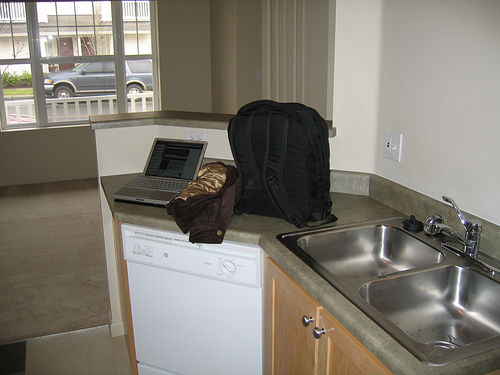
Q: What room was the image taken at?
A: It was taken at the kitchen.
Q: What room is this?
A: It is a kitchen.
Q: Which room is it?
A: It is a kitchen.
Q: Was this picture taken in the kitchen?
A: Yes, it was taken in the kitchen.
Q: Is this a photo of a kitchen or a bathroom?
A: It is showing a kitchen.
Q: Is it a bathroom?
A: No, it is a kitchen.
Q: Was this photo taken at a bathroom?
A: No, the picture was taken in a kitchen.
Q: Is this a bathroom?
A: No, it is a kitchen.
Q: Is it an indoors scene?
A: Yes, it is indoors.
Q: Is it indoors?
A: Yes, it is indoors.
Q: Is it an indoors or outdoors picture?
A: It is indoors.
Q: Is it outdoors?
A: No, it is indoors.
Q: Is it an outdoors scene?
A: No, it is indoors.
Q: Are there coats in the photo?
A: Yes, there is a coat.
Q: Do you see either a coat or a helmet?
A: Yes, there is a coat.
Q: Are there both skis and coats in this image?
A: No, there is a coat but no skis.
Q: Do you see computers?
A: Yes, there is a computer.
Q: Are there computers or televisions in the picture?
A: Yes, there is a computer.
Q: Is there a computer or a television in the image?
A: Yes, there is a computer.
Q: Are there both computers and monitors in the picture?
A: No, there is a computer but no monitors.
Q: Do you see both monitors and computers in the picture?
A: No, there is a computer but no monitors.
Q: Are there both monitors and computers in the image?
A: No, there is a computer but no monitors.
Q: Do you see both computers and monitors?
A: No, there is a computer but no monitors.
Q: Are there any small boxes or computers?
A: Yes, there is a small computer.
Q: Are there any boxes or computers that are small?
A: Yes, the computer is small.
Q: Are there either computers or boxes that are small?
A: Yes, the computer is small.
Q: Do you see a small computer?
A: Yes, there is a small computer.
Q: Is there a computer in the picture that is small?
A: Yes, there is a computer that is small.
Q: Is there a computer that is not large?
A: Yes, there is a small computer.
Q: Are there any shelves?
A: No, there are no shelves.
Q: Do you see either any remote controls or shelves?
A: No, there are no shelves or remote controls.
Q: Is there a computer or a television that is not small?
A: No, there is a computer but it is small.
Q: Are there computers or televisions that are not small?
A: No, there is a computer but it is small.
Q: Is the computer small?
A: Yes, the computer is small.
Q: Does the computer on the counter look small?
A: Yes, the computer is small.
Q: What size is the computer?
A: The computer is small.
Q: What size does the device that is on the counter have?
A: The computer has small size.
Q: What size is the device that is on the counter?
A: The computer is small.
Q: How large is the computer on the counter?
A: The computer is small.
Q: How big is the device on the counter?
A: The computer is small.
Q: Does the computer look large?
A: No, the computer is small.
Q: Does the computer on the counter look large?
A: No, the computer is small.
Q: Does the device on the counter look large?
A: No, the computer is small.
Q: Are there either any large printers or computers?
A: No, there is a computer but it is small.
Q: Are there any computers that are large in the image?
A: No, there is a computer but it is small.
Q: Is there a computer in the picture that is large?
A: No, there is a computer but it is small.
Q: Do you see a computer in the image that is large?
A: No, there is a computer but it is small.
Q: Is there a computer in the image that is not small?
A: No, there is a computer but it is small.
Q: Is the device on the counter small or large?
A: The computer is small.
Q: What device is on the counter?
A: The device is a computer.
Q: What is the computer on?
A: The computer is on the counter.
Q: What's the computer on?
A: The computer is on the counter.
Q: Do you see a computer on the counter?
A: Yes, there is a computer on the counter.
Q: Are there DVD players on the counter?
A: No, there is a computer on the counter.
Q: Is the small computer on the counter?
A: Yes, the computer is on the counter.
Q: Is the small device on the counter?
A: Yes, the computer is on the counter.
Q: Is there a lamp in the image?
A: No, there are no lamps.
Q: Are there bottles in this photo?
A: No, there are no bottles.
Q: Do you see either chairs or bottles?
A: No, there are no bottles or chairs.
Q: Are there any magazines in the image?
A: No, there are no magazines.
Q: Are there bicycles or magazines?
A: No, there are no magazines or bicycles.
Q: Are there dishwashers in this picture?
A: Yes, there is a dishwasher.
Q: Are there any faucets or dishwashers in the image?
A: Yes, there is a dishwasher.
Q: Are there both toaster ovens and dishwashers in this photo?
A: No, there is a dishwasher but no toaster ovens.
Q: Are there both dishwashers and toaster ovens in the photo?
A: No, there is a dishwasher but no toaster ovens.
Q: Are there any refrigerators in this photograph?
A: No, there are no refrigerators.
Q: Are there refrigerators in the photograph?
A: No, there are no refrigerators.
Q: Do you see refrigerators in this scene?
A: No, there are no refrigerators.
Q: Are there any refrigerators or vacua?
A: No, there are no refrigerators or vacua.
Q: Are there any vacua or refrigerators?
A: No, there are no refrigerators or vacua.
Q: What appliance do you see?
A: The appliance is a dishwasher.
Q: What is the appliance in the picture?
A: The appliance is a dishwasher.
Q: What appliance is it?
A: The appliance is a dishwasher.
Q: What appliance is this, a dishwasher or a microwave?
A: This is a dishwasher.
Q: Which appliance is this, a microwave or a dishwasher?
A: This is a dishwasher.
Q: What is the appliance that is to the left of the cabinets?
A: The appliance is a dishwasher.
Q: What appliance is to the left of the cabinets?
A: The appliance is a dishwasher.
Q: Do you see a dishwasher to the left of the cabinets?
A: Yes, there is a dishwasher to the left of the cabinets.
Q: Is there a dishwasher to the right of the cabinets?
A: No, the dishwasher is to the left of the cabinets.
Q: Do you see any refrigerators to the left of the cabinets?
A: No, there is a dishwasher to the left of the cabinets.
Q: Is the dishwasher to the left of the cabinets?
A: Yes, the dishwasher is to the left of the cabinets.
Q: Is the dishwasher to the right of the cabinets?
A: No, the dishwasher is to the left of the cabinets.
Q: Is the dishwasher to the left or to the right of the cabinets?
A: The dishwasher is to the left of the cabinets.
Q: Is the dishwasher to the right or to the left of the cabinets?
A: The dishwasher is to the left of the cabinets.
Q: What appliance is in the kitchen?
A: The appliance is a dishwasher.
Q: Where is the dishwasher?
A: The dishwasher is in the kitchen.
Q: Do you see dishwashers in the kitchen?
A: Yes, there is a dishwasher in the kitchen.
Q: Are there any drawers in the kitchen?
A: No, there is a dishwasher in the kitchen.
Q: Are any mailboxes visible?
A: No, there are no mailboxes.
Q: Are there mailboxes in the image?
A: No, there are no mailboxes.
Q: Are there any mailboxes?
A: No, there are no mailboxes.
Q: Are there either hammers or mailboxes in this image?
A: No, there are no mailboxes or hammers.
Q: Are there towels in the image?
A: No, there are no towels.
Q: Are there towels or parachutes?
A: No, there are no towels or parachutes.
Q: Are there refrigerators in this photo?
A: No, there are no refrigerators.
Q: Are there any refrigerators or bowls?
A: No, there are no refrigerators or bowls.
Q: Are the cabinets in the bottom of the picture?
A: Yes, the cabinets are in the bottom of the image.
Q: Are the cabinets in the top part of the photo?
A: No, the cabinets are in the bottom of the image.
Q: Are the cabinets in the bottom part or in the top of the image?
A: The cabinets are in the bottom of the image.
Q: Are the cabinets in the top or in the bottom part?
A: The cabinets are in the bottom of the image.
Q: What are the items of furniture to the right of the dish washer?
A: The pieces of furniture are cabinets.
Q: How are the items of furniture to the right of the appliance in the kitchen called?
A: The pieces of furniture are cabinets.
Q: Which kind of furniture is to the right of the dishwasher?
A: The pieces of furniture are cabinets.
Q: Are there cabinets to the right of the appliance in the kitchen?
A: Yes, there are cabinets to the right of the dishwasher.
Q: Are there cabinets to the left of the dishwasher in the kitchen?
A: No, the cabinets are to the right of the dish washer.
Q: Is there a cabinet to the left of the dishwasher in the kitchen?
A: No, the cabinets are to the right of the dish washer.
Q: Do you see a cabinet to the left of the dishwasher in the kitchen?
A: No, the cabinets are to the right of the dish washer.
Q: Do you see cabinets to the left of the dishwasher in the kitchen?
A: No, the cabinets are to the right of the dish washer.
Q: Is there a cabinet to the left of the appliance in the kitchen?
A: No, the cabinets are to the right of the dish washer.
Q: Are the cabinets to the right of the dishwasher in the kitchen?
A: Yes, the cabinets are to the right of the dishwasher.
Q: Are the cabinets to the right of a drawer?
A: No, the cabinets are to the right of the dishwasher.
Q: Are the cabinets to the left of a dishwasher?
A: No, the cabinets are to the right of a dishwasher.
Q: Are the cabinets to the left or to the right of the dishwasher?
A: The cabinets are to the right of the dishwasher.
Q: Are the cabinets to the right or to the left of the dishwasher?
A: The cabinets are to the right of the dishwasher.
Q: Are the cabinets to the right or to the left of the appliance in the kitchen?
A: The cabinets are to the right of the dishwasher.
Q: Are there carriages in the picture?
A: No, there are no carriages.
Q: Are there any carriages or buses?
A: No, there are no carriages or buses.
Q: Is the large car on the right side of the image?
A: No, the car is on the left of the image.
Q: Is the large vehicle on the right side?
A: No, the car is on the left of the image.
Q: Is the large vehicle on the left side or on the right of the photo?
A: The car is on the left of the image.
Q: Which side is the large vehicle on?
A: The car is on the left of the image.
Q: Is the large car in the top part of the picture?
A: Yes, the car is in the top of the image.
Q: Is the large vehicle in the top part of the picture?
A: Yes, the car is in the top of the image.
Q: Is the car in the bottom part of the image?
A: No, the car is in the top of the image.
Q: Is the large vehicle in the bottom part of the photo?
A: No, the car is in the top of the image.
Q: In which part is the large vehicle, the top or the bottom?
A: The car is in the top of the image.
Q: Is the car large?
A: Yes, the car is large.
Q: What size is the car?
A: The car is large.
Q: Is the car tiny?
A: No, the car is large.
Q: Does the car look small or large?
A: The car is large.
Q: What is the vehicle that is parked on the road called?
A: The vehicle is a car.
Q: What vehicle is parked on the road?
A: The vehicle is a car.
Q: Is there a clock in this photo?
A: No, there are no clocks.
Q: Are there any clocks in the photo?
A: No, there are no clocks.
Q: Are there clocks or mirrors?
A: No, there are no clocks or mirrors.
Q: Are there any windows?
A: Yes, there is a window.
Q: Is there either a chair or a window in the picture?
A: Yes, there is a window.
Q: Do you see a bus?
A: No, there are no buses.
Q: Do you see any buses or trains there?
A: No, there are no buses or trains.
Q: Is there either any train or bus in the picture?
A: No, there are no buses or trains.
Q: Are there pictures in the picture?
A: No, there are no pictures.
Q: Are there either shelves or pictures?
A: No, there are no pictures or shelves.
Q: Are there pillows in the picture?
A: No, there are no pillows.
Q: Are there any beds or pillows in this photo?
A: No, there are no pillows or beds.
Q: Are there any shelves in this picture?
A: No, there are no shelves.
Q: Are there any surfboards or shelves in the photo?
A: No, there are no shelves or surfboards.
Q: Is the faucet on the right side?
A: Yes, the faucet is on the right of the image.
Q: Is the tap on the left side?
A: No, the tap is on the right of the image.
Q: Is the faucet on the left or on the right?
A: The faucet is on the right of the image.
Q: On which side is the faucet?
A: The faucet is on the right of the image.